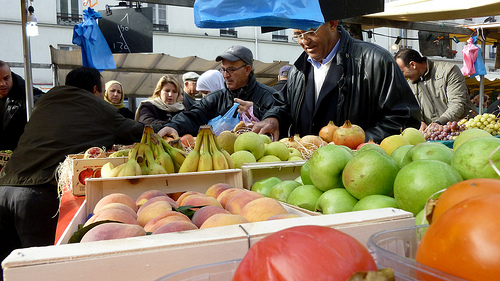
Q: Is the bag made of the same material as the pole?
A: No, the bag is made of plastic and the pole is made of metal.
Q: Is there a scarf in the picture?
A: Yes, there is a scarf.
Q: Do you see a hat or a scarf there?
A: Yes, there is a scarf.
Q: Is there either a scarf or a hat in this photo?
A: Yes, there is a scarf.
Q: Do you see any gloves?
A: No, there are no gloves.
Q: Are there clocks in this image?
A: No, there are no clocks.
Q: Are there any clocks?
A: No, there are no clocks.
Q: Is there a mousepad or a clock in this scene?
A: No, there are no clocks or mouse pads.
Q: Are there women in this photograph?
A: Yes, there is a woman.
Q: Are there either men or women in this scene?
A: Yes, there is a woman.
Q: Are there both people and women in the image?
A: Yes, there are both a woman and a person.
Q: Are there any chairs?
A: No, there are no chairs.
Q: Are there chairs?
A: No, there are no chairs.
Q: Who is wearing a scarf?
A: The woman is wearing a scarf.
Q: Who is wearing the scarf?
A: The woman is wearing a scarf.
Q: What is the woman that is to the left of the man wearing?
A: The woman is wearing a scarf.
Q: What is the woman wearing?
A: The woman is wearing a scarf.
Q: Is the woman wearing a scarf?
A: Yes, the woman is wearing a scarf.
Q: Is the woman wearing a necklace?
A: No, the woman is wearing a scarf.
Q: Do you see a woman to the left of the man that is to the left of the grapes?
A: Yes, there is a woman to the left of the man.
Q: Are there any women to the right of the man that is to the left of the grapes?
A: No, the woman is to the left of the man.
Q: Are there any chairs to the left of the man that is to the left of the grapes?
A: No, there is a woman to the left of the man.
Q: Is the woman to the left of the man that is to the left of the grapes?
A: Yes, the woman is to the left of the man.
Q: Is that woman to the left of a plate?
A: No, the woman is to the left of the man.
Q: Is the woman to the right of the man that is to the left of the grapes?
A: No, the woman is to the left of the man.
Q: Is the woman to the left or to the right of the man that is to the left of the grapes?
A: The woman is to the left of the man.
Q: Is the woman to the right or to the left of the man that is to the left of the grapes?
A: The woman is to the left of the man.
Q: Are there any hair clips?
A: No, there are no hair clips.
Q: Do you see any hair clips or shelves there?
A: No, there are no hair clips or shelves.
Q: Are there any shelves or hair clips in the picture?
A: No, there are no hair clips or shelves.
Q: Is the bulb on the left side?
A: Yes, the bulb is on the left of the image.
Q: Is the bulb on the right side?
A: No, the bulb is on the left of the image.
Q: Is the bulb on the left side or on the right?
A: The bulb is on the left of the image.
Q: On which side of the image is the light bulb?
A: The light bulb is on the left of the image.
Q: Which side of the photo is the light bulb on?
A: The light bulb is on the left of the image.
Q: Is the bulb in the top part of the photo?
A: Yes, the bulb is in the top of the image.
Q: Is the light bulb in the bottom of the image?
A: No, the light bulb is in the top of the image.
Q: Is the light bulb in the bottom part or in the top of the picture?
A: The light bulb is in the top of the image.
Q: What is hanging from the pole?
A: The bulb is hanging from the pole.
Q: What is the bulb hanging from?
A: The bulb is hanging from the pole.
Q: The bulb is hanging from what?
A: The bulb is hanging from the pole.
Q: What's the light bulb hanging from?
A: The bulb is hanging from the pole.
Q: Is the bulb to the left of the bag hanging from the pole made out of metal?
A: Yes, the light bulb is hanging from the pole.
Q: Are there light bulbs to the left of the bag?
A: Yes, there is a light bulb to the left of the bag.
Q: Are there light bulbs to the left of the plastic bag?
A: Yes, there is a light bulb to the left of the bag.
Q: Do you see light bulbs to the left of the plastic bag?
A: Yes, there is a light bulb to the left of the bag.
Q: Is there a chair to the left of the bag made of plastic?
A: No, there is a light bulb to the left of the bag.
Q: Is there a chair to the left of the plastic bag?
A: No, there is a light bulb to the left of the bag.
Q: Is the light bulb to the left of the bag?
A: Yes, the light bulb is to the left of the bag.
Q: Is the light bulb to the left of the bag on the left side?
A: Yes, the light bulb is to the left of the bag.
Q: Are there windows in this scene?
A: Yes, there are windows.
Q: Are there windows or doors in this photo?
A: Yes, there are windows.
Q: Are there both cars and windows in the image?
A: No, there are windows but no cars.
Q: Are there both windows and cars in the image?
A: No, there are windows but no cars.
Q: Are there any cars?
A: No, there are no cars.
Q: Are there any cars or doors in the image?
A: No, there are no cars or doors.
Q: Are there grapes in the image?
A: Yes, there are grapes.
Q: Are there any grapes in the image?
A: Yes, there are grapes.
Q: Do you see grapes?
A: Yes, there are grapes.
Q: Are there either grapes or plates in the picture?
A: Yes, there are grapes.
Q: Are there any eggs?
A: No, there are no eggs.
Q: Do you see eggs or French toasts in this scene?
A: No, there are no eggs or French toasts.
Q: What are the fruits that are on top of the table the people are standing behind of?
A: The fruits are grapes.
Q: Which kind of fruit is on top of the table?
A: The fruits are grapes.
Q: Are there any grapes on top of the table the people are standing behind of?
A: Yes, there are grapes on top of the table.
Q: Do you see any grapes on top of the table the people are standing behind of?
A: Yes, there are grapes on top of the table.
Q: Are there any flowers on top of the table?
A: No, there are grapes on top of the table.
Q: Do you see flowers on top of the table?
A: No, there are grapes on top of the table.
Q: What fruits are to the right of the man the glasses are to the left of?
A: The fruits are grapes.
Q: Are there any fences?
A: No, there are no fences.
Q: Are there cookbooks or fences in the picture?
A: No, there are no fences or cookbooks.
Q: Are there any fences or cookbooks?
A: No, there are no fences or cookbooks.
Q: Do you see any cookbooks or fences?
A: No, there are no fences or cookbooks.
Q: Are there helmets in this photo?
A: No, there are no helmets.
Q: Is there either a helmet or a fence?
A: No, there are no helmets or fences.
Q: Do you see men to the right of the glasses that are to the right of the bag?
A: Yes, there is a man to the right of the glasses.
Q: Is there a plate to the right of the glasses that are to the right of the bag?
A: No, there is a man to the right of the glasses.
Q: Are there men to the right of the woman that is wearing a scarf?
A: Yes, there is a man to the right of the woman.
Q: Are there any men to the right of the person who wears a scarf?
A: Yes, there is a man to the right of the woman.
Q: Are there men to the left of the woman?
A: No, the man is to the right of the woman.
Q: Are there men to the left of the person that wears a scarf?
A: No, the man is to the right of the woman.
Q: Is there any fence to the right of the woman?
A: No, there is a man to the right of the woman.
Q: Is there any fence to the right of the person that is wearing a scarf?
A: No, there is a man to the right of the woman.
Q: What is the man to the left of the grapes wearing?
A: The man is wearing glasses.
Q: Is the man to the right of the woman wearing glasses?
A: Yes, the man is wearing glasses.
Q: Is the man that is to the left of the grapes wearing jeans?
A: No, the man is wearing glasses.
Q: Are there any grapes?
A: Yes, there are grapes.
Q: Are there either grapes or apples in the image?
A: Yes, there are grapes.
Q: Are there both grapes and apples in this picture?
A: Yes, there are both grapes and apples.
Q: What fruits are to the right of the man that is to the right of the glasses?
A: The fruits are grapes.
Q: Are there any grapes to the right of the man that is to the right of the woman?
A: Yes, there are grapes to the right of the man.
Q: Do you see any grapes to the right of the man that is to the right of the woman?
A: Yes, there are grapes to the right of the man.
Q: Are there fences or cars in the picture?
A: No, there are no cars or fences.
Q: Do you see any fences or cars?
A: No, there are no cars or fences.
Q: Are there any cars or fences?
A: No, there are no cars or fences.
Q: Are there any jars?
A: No, there are no jars.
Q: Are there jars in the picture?
A: No, there are no jars.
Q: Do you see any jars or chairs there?
A: No, there are no jars or chairs.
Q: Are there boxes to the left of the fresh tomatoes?
A: Yes, there is a box to the left of the tomatoes.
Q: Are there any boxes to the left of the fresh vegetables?
A: Yes, there is a box to the left of the tomatoes.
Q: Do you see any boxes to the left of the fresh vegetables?
A: Yes, there is a box to the left of the tomatoes.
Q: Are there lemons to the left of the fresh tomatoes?
A: No, there is a box to the left of the tomatoes.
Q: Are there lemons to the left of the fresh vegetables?
A: No, there is a box to the left of the tomatoes.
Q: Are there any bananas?
A: Yes, there are bananas.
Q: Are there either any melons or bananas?
A: Yes, there are bananas.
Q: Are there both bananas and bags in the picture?
A: Yes, there are both bananas and a bag.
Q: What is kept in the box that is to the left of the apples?
A: The bananas are kept in the box.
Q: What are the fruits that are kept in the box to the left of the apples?
A: The fruits are bananas.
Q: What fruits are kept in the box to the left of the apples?
A: The fruits are bananas.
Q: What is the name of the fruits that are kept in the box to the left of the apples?
A: The fruits are bananas.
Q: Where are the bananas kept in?
A: The bananas are kept in the box.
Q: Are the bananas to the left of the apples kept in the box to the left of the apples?
A: Yes, the bananas are kept in the box.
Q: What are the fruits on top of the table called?
A: The fruits are bananas.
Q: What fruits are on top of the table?
A: The fruits are bananas.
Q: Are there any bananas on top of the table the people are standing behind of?
A: Yes, there are bananas on top of the table.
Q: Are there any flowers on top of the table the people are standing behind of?
A: No, there are bananas on top of the table.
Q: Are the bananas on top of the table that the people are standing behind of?
A: Yes, the bananas are on top of the table.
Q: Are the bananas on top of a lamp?
A: No, the bananas are on top of the table.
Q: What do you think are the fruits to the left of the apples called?
A: The fruits are bananas.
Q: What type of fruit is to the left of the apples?
A: The fruits are bananas.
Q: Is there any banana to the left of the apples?
A: Yes, there are bananas to the left of the apples.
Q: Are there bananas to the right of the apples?
A: No, the bananas are to the left of the apples.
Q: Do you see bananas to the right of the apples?
A: No, the bananas are to the left of the apples.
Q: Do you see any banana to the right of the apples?
A: No, the bananas are to the left of the apples.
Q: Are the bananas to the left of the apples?
A: Yes, the bananas are to the left of the apples.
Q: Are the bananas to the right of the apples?
A: No, the bananas are to the left of the apples.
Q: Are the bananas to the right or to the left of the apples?
A: The bananas are to the left of the apples.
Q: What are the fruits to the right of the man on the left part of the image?
A: The fruits are bananas.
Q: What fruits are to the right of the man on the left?
A: The fruits are bananas.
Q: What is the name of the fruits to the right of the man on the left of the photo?
A: The fruits are bananas.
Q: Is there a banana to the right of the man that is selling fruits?
A: Yes, there are bananas to the right of the man.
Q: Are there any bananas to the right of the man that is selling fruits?
A: Yes, there are bananas to the right of the man.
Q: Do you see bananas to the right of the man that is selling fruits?
A: Yes, there are bananas to the right of the man.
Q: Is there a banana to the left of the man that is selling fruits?
A: No, the bananas are to the right of the man.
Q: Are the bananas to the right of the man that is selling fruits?
A: Yes, the bananas are to the right of the man.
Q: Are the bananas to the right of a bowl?
A: No, the bananas are to the right of the man.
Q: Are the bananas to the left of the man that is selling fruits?
A: No, the bananas are to the right of the man.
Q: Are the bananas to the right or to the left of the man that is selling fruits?
A: The bananas are to the right of the man.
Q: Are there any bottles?
A: No, there are no bottles.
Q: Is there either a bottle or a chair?
A: No, there are no bottles or chairs.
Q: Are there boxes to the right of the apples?
A: No, the box is to the left of the apples.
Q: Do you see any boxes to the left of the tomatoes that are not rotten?
A: Yes, there is a box to the left of the tomatoes.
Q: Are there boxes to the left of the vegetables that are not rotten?
A: Yes, there is a box to the left of the tomatoes.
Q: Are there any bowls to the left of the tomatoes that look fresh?
A: No, there is a box to the left of the tomatoes.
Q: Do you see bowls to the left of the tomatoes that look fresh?
A: No, there is a box to the left of the tomatoes.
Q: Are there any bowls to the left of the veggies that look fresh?
A: No, there is a box to the left of the tomatoes.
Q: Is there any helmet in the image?
A: No, there are no helmets.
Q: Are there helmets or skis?
A: No, there are no helmets or skis.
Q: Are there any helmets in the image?
A: No, there are no helmets.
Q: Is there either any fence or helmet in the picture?
A: No, there are no helmets or fences.